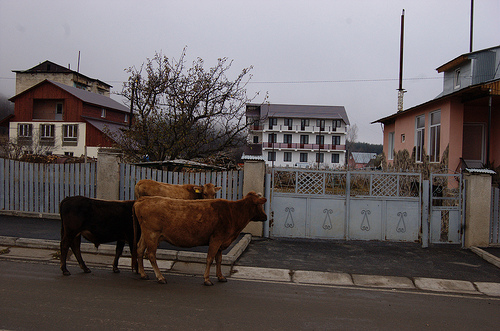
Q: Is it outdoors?
A: Yes, it is outdoors.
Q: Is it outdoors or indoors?
A: It is outdoors.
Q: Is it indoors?
A: No, it is outdoors.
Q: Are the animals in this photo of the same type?
A: Yes, all the animals are cows.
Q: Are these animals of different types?
A: No, all the animals are cows.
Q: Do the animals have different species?
A: No, all the animals are cows.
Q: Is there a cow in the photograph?
A: Yes, there is a cow.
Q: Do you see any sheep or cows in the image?
A: Yes, there is a cow.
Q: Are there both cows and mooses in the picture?
A: No, there is a cow but no mooses.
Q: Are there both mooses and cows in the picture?
A: No, there is a cow but no mooses.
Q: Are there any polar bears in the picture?
A: No, there are no polar bears.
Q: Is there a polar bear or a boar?
A: No, there are no polar bears or boars.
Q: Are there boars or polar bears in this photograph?
A: No, there are no polar bears or boars.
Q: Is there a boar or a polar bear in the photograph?
A: No, there are no polar bears or boars.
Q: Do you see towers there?
A: No, there are no towers.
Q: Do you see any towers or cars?
A: No, there are no towers or cars.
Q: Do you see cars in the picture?
A: No, there are no cars.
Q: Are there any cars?
A: No, there are no cars.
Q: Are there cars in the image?
A: No, there are no cars.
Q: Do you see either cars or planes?
A: No, there are no cars or planes.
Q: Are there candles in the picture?
A: No, there are no candles.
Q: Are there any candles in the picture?
A: No, there are no candles.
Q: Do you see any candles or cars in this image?
A: No, there are no candles or cars.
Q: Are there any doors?
A: Yes, there is a door.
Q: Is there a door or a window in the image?
A: Yes, there is a door.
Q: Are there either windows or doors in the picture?
A: Yes, there is a door.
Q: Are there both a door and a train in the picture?
A: No, there is a door but no trains.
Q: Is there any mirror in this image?
A: No, there are no mirrors.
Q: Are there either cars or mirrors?
A: No, there are no mirrors or cars.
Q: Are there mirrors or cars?
A: No, there are no mirrors or cars.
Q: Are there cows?
A: Yes, there is a cow.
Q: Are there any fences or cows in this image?
A: Yes, there is a cow.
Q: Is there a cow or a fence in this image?
A: Yes, there is a cow.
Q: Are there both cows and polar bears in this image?
A: No, there is a cow but no polar bears.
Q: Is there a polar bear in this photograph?
A: No, there are no polar bears.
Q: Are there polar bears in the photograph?
A: No, there are no polar bears.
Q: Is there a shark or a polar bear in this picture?
A: No, there are no polar bears or sharks.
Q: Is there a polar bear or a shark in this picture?
A: No, there are no polar bears or sharks.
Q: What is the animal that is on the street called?
A: The animal is a cow.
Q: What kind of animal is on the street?
A: The animal is a cow.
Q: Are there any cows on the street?
A: Yes, there is a cow on the street.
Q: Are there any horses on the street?
A: No, there is a cow on the street.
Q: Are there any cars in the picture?
A: No, there are no cars.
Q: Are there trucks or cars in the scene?
A: No, there are no cars or trucks.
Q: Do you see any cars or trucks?
A: No, there are no cars or trucks.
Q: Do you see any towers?
A: No, there are no towers.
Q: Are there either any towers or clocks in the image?
A: No, there are no towers or clocks.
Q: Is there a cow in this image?
A: Yes, there is a cow.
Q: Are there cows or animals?
A: Yes, there is a cow.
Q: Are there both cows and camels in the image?
A: No, there is a cow but no camels.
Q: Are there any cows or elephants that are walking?
A: Yes, the cow is walking.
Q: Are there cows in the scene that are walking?
A: Yes, there is a cow that is walking.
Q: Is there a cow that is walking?
A: Yes, there is a cow that is walking.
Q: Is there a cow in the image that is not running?
A: Yes, there is a cow that is walking.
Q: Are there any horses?
A: No, there are no horses.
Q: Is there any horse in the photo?
A: No, there are no horses.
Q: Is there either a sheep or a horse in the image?
A: No, there are no horses or sheep.